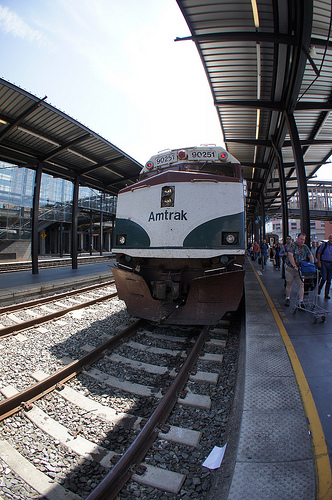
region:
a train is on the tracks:
[110, 143, 243, 369]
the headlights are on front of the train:
[115, 180, 243, 269]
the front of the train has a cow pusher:
[105, 263, 246, 336]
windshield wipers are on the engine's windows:
[138, 159, 238, 184]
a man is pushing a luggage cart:
[281, 229, 327, 324]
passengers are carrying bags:
[249, 237, 274, 273]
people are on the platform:
[229, 152, 331, 333]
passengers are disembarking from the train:
[245, 219, 330, 329]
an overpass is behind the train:
[10, 181, 331, 268]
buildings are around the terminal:
[2, 161, 331, 275]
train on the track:
[98, 135, 245, 349]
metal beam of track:
[150, 403, 188, 441]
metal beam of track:
[19, 385, 43, 403]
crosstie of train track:
[44, 416, 91, 453]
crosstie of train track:
[9, 449, 42, 486]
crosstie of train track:
[92, 399, 115, 430]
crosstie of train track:
[114, 372, 147, 398]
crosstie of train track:
[117, 354, 148, 373]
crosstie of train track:
[135, 342, 151, 357]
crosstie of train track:
[141, 340, 157, 354]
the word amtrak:
[149, 209, 186, 222]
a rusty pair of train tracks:
[1, 317, 232, 498]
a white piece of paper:
[199, 441, 227, 473]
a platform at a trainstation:
[246, 245, 331, 494]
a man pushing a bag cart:
[283, 232, 327, 322]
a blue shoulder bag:
[297, 261, 315, 284]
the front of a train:
[111, 146, 247, 325]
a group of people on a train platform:
[247, 231, 330, 313]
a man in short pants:
[285, 232, 312, 305]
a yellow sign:
[38, 231, 48, 255]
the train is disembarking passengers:
[2, 2, 330, 496]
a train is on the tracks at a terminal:
[100, 145, 243, 400]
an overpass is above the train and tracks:
[9, 181, 331, 287]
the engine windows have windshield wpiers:
[143, 159, 240, 181]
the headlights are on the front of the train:
[115, 182, 242, 250]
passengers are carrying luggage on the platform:
[249, 236, 285, 276]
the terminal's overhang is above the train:
[119, 1, 331, 309]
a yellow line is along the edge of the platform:
[244, 243, 331, 499]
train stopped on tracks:
[106, 141, 250, 328]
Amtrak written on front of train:
[140, 209, 187, 226]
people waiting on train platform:
[249, 221, 330, 332]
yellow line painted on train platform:
[246, 252, 329, 499]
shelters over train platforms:
[3, 14, 327, 279]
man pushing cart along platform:
[285, 233, 328, 318]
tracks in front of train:
[9, 323, 216, 498]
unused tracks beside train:
[0, 260, 117, 333]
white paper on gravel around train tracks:
[197, 439, 224, 467]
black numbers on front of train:
[153, 149, 219, 163]